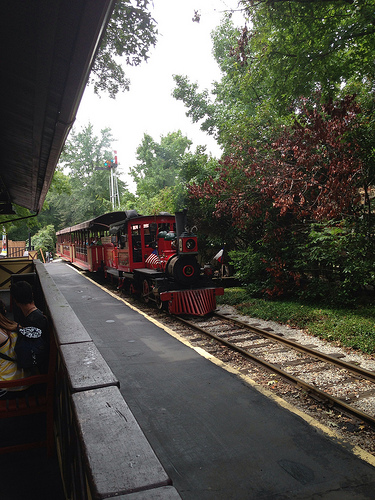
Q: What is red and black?
A: Train.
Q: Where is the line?
A: On platform.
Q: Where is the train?
A: On track.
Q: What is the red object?
A: Train.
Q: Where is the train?
A: On track.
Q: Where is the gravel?
A: The track.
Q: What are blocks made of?
A: Concrete.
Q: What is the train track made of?
A: Metal.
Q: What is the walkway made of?
A: Asphalt.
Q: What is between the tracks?
A: Gravel.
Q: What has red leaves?
A: Tree.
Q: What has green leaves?
A: Tree.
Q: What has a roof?
A: The station.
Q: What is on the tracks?
A: Red train.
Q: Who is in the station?
A: The man in the t-shirt.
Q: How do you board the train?
A: The platform.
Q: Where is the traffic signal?
A: Above the train.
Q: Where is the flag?
A: On the train.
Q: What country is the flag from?
A: United States.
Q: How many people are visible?
A: One.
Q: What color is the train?
A: Red and black.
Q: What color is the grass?
A: Green.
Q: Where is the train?
A: On the tracks.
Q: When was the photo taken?
A: Daytime.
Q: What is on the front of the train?
A: An American flag.